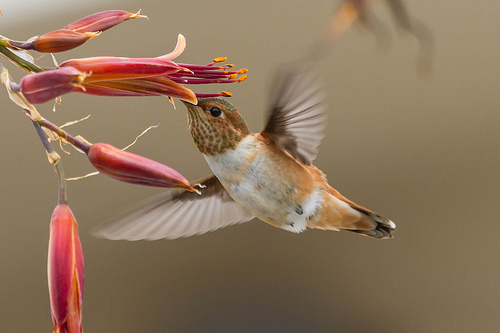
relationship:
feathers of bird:
[338, 187, 398, 244] [121, 63, 401, 258]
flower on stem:
[47, 203, 87, 331] [28, 116, 74, 197]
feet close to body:
[273, 201, 305, 231] [219, 126, 330, 227]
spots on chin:
[205, 132, 223, 150] [199, 119, 230, 149]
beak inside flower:
[183, 95, 203, 113] [62, 50, 252, 100]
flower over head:
[62, 50, 252, 100] [180, 83, 260, 160]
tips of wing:
[88, 217, 233, 241] [94, 173, 264, 245]